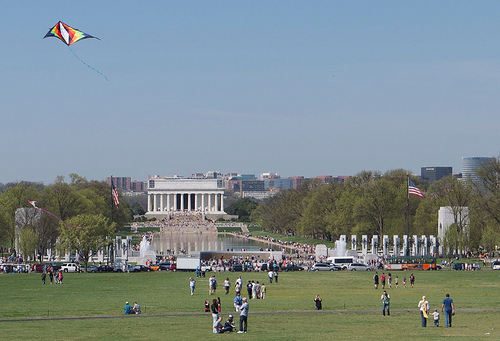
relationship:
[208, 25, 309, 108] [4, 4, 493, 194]
clouds in sky